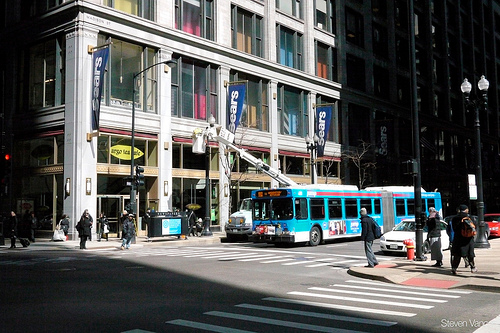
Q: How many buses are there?
A: One.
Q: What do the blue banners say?
A: Sears.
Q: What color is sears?
A: White.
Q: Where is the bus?
A: In the street.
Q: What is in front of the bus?
A: A crosswalk.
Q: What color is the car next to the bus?
A: White.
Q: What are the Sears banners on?
A: A building.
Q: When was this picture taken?
A: During the day.